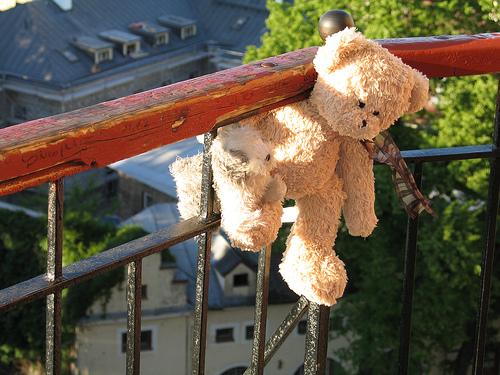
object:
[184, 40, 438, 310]
bear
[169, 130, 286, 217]
toy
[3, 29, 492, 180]
wood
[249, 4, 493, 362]
tree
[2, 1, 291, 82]
roof